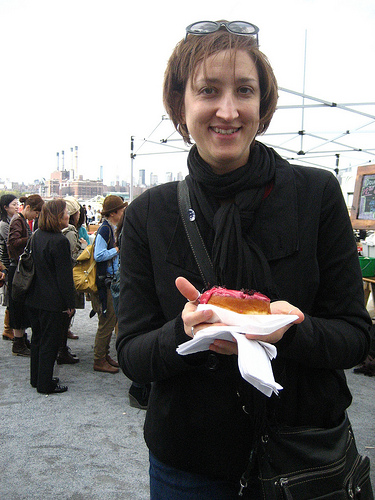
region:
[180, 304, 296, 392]
White napkins.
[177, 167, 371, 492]
A black crossbody bag.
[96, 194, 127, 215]
A brown hat.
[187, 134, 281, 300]
A black scarf.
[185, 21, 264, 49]
A pair of black framed glasses.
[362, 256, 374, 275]
A green bucket.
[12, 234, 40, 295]
A black shoulder bag.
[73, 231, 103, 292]
A yellow backpack.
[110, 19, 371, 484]
A woman holding a pastry.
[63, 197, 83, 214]
A beige hat.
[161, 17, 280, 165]
Woman with light brown hair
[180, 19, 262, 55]
Glasses on top of a woman's head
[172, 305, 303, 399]
Two stacks of white napkins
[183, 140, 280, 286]
Black neck scarf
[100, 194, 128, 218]
Dark brown hat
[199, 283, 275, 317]
Dessert with red topping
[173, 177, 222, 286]
Black shoulder strap of purse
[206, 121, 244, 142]
Smile on a woman's face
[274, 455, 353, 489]
Zipper on womans purse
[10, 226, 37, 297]
Black should bag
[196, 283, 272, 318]
A cake like food.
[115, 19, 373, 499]
A woman wearing black.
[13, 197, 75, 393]
A woman in a black suit.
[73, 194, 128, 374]
A person with a yellow backpack.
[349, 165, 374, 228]
A handwritten chalkboard sign.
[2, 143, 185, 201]
Distant city buildings.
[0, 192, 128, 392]
A group of people waiting in line.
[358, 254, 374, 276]
A small green bucket.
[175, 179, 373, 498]
A black shoulder bag.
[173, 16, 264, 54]
woman with glasses on her head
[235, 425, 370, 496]
woman with pocket book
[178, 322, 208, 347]
woman wearing wedding ring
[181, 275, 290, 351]
woman holding a wedding ring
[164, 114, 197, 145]
woman wearing silver earrings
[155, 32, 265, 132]
woman with short cropped hair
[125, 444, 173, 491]
woman wearing blue jeans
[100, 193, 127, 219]
woman wearing brown hats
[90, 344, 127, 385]
woman wearing brown boots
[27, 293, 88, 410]
woman wearing black bears